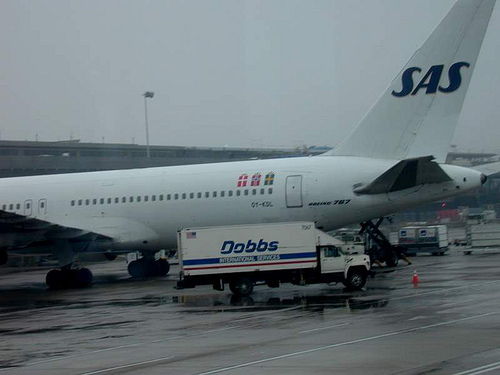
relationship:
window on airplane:
[66, 198, 76, 208] [0, 2, 496, 292]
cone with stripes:
[407, 264, 422, 287] [411, 270, 419, 277]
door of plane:
[282, 172, 305, 210] [0, 9, 495, 297]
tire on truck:
[341, 267, 368, 291] [175, 217, 371, 298]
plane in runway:
[0, 9, 495, 297] [0, 242, 498, 373]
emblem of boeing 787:
[306, 197, 351, 208] [0, 0, 497, 288]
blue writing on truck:
[223, 238, 280, 256] [172, 217, 380, 302]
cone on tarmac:
[412, 269, 419, 285] [1, 256, 499, 372]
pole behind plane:
[138, 87, 159, 160] [0, 9, 495, 297]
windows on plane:
[0, 183, 275, 213] [0, 9, 495, 297]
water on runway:
[64, 288, 311, 313] [4, 269, 499, 373]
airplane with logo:
[0, 2, 496, 292] [236, 174, 248, 191]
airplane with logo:
[0, 2, 496, 292] [247, 169, 265, 189]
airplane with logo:
[0, 2, 496, 292] [264, 171, 275, 189]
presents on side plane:
[232, 170, 276, 190] [82, 79, 487, 351]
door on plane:
[284, 168, 319, 220] [14, 26, 499, 315]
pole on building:
[136, 89, 156, 166] [2, 135, 239, 175]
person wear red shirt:
[413, 270, 420, 287] [411, 274, 421, 284]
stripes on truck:
[167, 225, 359, 293] [175, 222, 445, 307]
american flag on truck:
[183, 230, 203, 248] [173, 220, 373, 282]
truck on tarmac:
[172, 217, 380, 302] [187, 284, 410, 344]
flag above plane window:
[261, 167, 276, 189] [201, 188, 213, 200]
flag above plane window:
[251, 170, 262, 190] [157, 190, 167, 205]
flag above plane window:
[232, 173, 249, 191] [95, 196, 103, 211]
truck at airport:
[173, 223, 379, 298] [63, 118, 445, 370]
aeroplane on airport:
[2, 1, 494, 303] [39, 107, 424, 333]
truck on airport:
[167, 219, 377, 295] [39, 107, 424, 333]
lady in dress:
[409, 266, 420, 287] [407, 270, 423, 289]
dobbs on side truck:
[213, 237, 286, 252] [167, 219, 377, 295]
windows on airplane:
[69, 196, 305, 205] [0, 2, 496, 292]